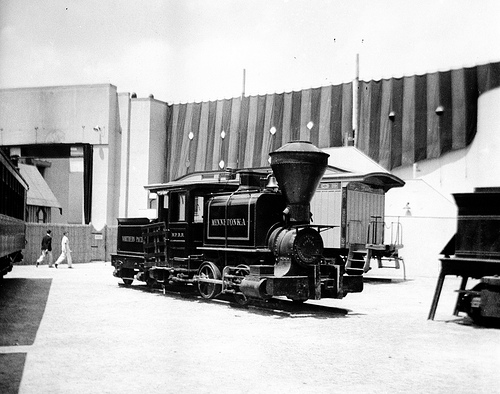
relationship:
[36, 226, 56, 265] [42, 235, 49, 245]
man in coat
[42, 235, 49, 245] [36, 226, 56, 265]
coat on man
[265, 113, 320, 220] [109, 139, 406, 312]
stack on locomotive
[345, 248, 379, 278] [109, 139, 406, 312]
steps on locomotive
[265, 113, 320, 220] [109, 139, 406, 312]
stack of locomotive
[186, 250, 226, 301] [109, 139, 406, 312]
wheel of locomotive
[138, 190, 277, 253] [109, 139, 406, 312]
cab on locomotive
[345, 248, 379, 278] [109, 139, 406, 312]
steps of locomotive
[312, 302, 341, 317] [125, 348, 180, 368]
shadows on ground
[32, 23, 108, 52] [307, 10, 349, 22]
sky with clouds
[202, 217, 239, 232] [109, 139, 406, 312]
lettering on locomotive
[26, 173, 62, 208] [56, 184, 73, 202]
tent over wall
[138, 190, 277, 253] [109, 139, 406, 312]
cab of locomotive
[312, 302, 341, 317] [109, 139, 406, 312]
shadows of locomotive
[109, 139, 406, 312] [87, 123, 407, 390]
locomotive behind locomotive